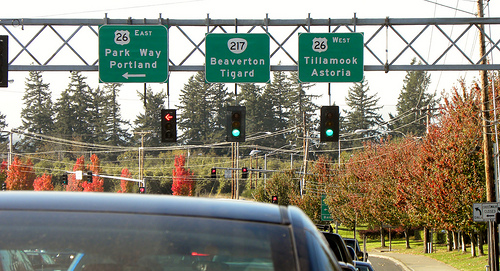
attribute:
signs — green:
[103, 26, 370, 83]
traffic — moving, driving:
[0, 177, 372, 260]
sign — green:
[206, 34, 271, 81]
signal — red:
[159, 105, 175, 142]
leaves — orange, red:
[352, 137, 472, 196]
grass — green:
[416, 221, 477, 265]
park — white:
[327, 132, 443, 198]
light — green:
[229, 127, 242, 137]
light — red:
[157, 107, 176, 136]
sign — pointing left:
[159, 106, 179, 140]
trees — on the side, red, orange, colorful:
[348, 113, 481, 215]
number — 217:
[221, 33, 251, 56]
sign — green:
[296, 31, 364, 81]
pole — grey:
[371, 14, 496, 36]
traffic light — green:
[221, 102, 247, 141]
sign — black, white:
[470, 198, 498, 219]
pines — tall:
[32, 70, 431, 208]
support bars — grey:
[19, 18, 94, 64]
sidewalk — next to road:
[372, 237, 456, 271]